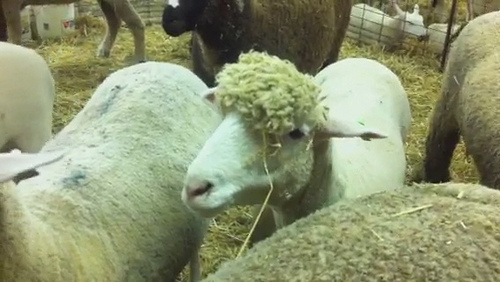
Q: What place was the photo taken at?
A: It was taken at the pen.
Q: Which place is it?
A: It is a pen.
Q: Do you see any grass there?
A: Yes, there is grass.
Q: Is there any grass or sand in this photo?
A: Yes, there is grass.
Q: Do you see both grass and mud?
A: No, there is grass but no mud.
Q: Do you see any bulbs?
A: No, there are no bulbs.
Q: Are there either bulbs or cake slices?
A: No, there are no bulbs or cake slices.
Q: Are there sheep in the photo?
A: Yes, there is a sheep.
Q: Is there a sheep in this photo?
A: Yes, there is a sheep.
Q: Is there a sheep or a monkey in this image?
A: Yes, there is a sheep.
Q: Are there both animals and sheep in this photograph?
A: Yes, there are both a sheep and animals.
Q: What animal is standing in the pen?
A: The sheep is standing in the pen.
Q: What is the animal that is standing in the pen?
A: The animal is a sheep.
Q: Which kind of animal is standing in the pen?
A: The animal is a sheep.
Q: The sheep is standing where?
A: The sheep is standing in the pen.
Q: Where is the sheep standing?
A: The sheep is standing in the pen.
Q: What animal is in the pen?
A: The sheep is in the pen.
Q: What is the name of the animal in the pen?
A: The animal is a sheep.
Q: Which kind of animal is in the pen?
A: The animal is a sheep.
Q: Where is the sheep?
A: The sheep is in the pen.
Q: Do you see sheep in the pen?
A: Yes, there is a sheep in the pen.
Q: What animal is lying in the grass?
A: The sheep is lying in the grass.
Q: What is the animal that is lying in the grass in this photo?
A: The animal is a sheep.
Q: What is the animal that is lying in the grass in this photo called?
A: The animal is a sheep.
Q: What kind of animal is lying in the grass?
A: The animal is a sheep.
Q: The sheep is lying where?
A: The sheep is lying in the grass.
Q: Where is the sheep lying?
A: The sheep is lying in the grass.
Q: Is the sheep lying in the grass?
A: Yes, the sheep is lying in the grass.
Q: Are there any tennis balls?
A: No, there are no tennis balls.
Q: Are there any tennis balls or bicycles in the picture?
A: No, there are no tennis balls or bicycles.